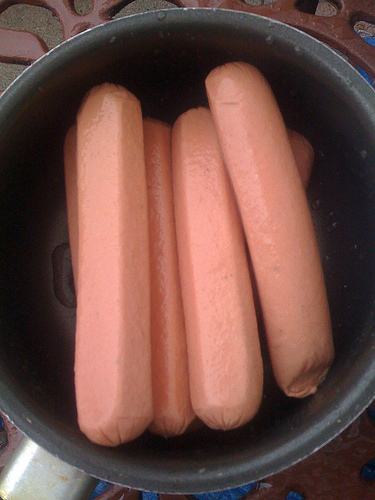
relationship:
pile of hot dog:
[61, 74, 314, 430] [78, 84, 140, 438]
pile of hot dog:
[61, 74, 314, 430] [178, 123, 232, 414]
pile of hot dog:
[61, 74, 314, 430] [231, 71, 322, 374]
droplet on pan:
[152, 9, 167, 24] [0, 5, 375, 500]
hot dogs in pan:
[63, 60, 336, 451] [0, 5, 375, 500]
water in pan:
[50, 241, 77, 310] [0, 5, 375, 500]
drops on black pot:
[152, 1, 313, 56] [0, 6, 374, 494]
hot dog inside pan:
[203, 63, 340, 399] [0, 10, 370, 487]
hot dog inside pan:
[140, 118, 193, 433] [0, 10, 370, 487]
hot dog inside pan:
[175, 104, 265, 435] [0, 10, 370, 487]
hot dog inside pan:
[72, 82, 153, 446] [0, 10, 370, 487]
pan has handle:
[0, 10, 370, 487] [2, 425, 88, 498]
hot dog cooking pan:
[73, 83, 154, 447] [0, 10, 370, 487]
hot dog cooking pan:
[141, 116, 202, 438] [0, 10, 370, 487]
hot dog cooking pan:
[171, 106, 264, 430] [0, 10, 370, 487]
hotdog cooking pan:
[205, 60, 334, 397] [0, 10, 370, 487]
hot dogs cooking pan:
[246, 129, 314, 319] [0, 10, 370, 487]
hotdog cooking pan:
[62, 124, 79, 293] [0, 10, 370, 487]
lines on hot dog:
[197, 403, 251, 430] [171, 106, 264, 430]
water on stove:
[316, 188, 361, 259] [275, 4, 374, 54]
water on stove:
[48, 243, 72, 305] [4, 3, 118, 44]